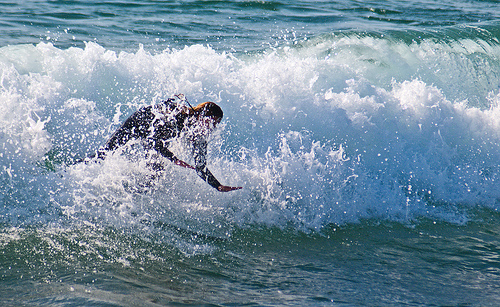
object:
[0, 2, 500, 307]
water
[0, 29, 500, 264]
wave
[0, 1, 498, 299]
ocean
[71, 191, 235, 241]
surfboard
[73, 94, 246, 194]
person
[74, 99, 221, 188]
black suit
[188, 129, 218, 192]
arm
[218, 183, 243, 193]
hand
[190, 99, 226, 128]
head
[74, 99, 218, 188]
body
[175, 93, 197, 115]
string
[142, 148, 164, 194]
legs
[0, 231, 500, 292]
ripples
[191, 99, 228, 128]
hair